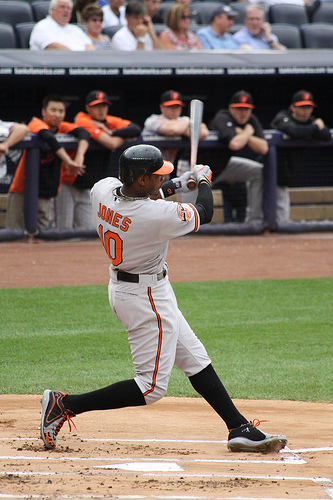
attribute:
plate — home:
[114, 431, 215, 492]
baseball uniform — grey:
[88, 176, 211, 406]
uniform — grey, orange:
[84, 162, 225, 408]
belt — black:
[114, 269, 166, 284]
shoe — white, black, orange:
[39, 388, 70, 450]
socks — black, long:
[187, 362, 248, 430]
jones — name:
[96, 201, 130, 231]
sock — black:
[188, 363, 249, 431]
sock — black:
[62, 378, 145, 415]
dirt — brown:
[134, 419, 180, 435]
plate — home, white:
[92, 451, 192, 490]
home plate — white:
[91, 458, 183, 476]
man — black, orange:
[39, 144, 290, 455]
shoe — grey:
[224, 418, 287, 453]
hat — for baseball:
[293, 87, 315, 107]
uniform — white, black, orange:
[87, 194, 210, 404]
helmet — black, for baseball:
[104, 127, 185, 197]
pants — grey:
[103, 264, 217, 406]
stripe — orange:
[133, 282, 169, 400]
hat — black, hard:
[115, 142, 177, 183]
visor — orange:
[149, 160, 174, 175]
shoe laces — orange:
[49, 410, 74, 436]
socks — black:
[64, 360, 249, 427]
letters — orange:
[95, 198, 128, 233]